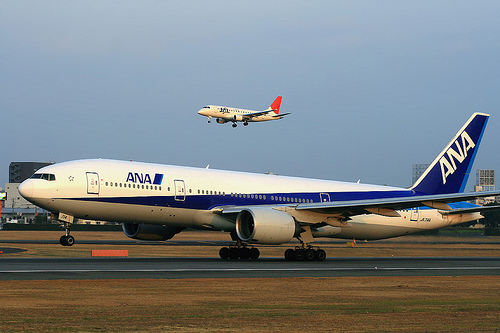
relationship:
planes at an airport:
[37, 64, 383, 324] [9, 6, 499, 330]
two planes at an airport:
[37, 64, 383, 324] [9, 6, 499, 330]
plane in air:
[200, 100, 287, 128] [131, 35, 321, 150]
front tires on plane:
[55, 231, 79, 253] [200, 100, 287, 128]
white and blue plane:
[35, 109, 499, 254] [200, 100, 287, 128]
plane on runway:
[200, 100, 287, 128] [68, 261, 221, 294]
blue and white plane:
[427, 174, 435, 190] [200, 100, 287, 128]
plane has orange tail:
[200, 100, 287, 128] [269, 96, 288, 119]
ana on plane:
[428, 121, 485, 194] [200, 100, 287, 128]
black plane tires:
[210, 244, 331, 262] [206, 234, 351, 267]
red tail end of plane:
[268, 82, 297, 140] [200, 100, 287, 128]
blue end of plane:
[427, 174, 435, 190] [200, 100, 287, 128]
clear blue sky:
[86, 21, 299, 81] [28, 27, 442, 85]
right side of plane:
[85, 149, 474, 270] [200, 100, 287, 128]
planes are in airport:
[37, 64, 383, 324] [9, 6, 499, 330]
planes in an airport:
[37, 64, 383, 324] [9, 6, 499, 330]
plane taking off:
[200, 100, 287, 128] [37, 200, 340, 324]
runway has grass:
[68, 261, 221, 294] [110, 274, 315, 332]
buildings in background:
[23, 206, 180, 236] [406, 154, 500, 226]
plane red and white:
[200, 100, 287, 128] [35, 109, 499, 254]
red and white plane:
[269, 89, 286, 125] [200, 100, 287, 128]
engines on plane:
[181, 194, 316, 270] [200, 100, 287, 128]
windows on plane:
[110, 175, 345, 223] [200, 100, 287, 128]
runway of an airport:
[68, 261, 221, 294] [9, 6, 499, 330]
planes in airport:
[37, 64, 383, 324] [9, 6, 499, 330]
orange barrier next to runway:
[91, 250, 124, 257] [68, 261, 221, 294]